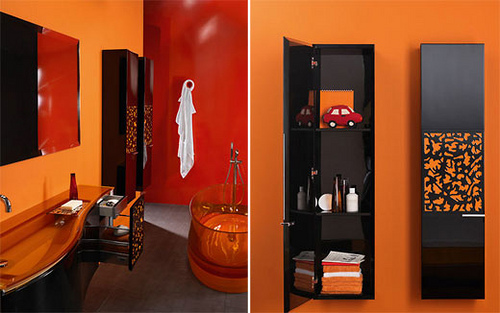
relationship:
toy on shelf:
[322, 104, 364, 129] [314, 127, 371, 132]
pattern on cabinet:
[423, 131, 484, 212] [419, 42, 485, 300]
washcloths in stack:
[321, 266, 364, 295] [321, 262, 363, 295]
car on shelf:
[322, 104, 364, 129] [314, 127, 371, 132]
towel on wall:
[175, 81, 197, 179] [143, 1, 248, 212]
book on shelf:
[321, 261, 361, 267] [315, 294, 375, 300]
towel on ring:
[175, 81, 197, 179] [184, 79, 195, 90]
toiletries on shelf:
[317, 176, 360, 212] [311, 212, 370, 216]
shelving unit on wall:
[419, 42, 485, 300] [251, 0, 500, 313]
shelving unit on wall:
[281, 35, 376, 312] [251, 0, 500, 313]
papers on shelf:
[320, 249, 367, 264] [315, 294, 375, 300]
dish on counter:
[48, 201, 90, 216] [1, 184, 115, 294]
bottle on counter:
[68, 172, 78, 202] [1, 184, 115, 294]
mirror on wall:
[34, 22, 82, 156] [0, 0, 143, 219]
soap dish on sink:
[48, 201, 90, 216] [1, 195, 93, 279]